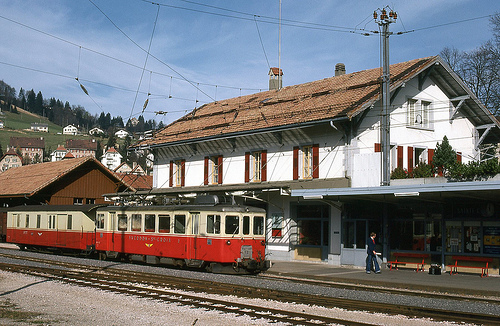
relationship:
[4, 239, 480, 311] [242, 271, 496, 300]
gravel by track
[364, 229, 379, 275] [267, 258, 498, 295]
person on platform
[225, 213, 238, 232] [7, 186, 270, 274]
windshield on tram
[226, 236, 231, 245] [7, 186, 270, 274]
light on tram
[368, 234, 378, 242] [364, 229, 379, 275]
head of person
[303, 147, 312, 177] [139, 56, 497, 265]
window on building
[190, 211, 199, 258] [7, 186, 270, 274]
door on tram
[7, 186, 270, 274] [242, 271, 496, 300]
tram on track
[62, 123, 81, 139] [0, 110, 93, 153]
house on grass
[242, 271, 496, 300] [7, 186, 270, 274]
track by tram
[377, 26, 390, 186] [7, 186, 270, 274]
pole by tram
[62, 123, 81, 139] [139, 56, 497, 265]
house behind building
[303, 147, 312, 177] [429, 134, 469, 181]
window by plant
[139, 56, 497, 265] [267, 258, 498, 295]
building by platform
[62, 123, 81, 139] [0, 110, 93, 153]
house in grass